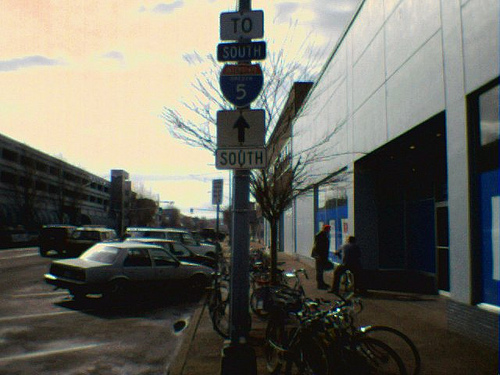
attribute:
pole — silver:
[217, 205, 263, 373]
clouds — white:
[95, 132, 152, 169]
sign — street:
[219, 58, 271, 105]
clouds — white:
[88, 61, 208, 131]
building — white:
[302, 20, 482, 162]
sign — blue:
[213, 35, 278, 121]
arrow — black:
[230, 112, 253, 144]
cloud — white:
[3, 11, 327, 214]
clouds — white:
[1, 46, 123, 76]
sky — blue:
[5, 1, 356, 221]